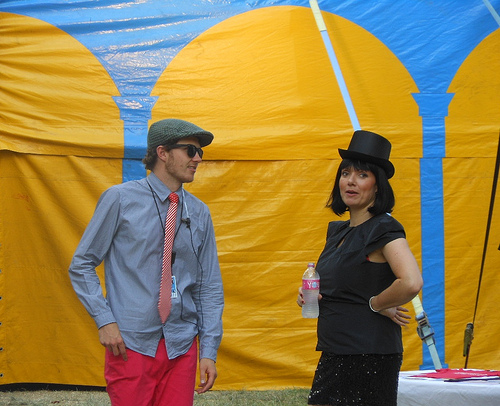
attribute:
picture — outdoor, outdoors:
[2, 1, 495, 403]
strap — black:
[453, 181, 496, 377]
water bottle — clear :
[297, 263, 319, 321]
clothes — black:
[303, 150, 433, 381]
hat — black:
[243, 95, 436, 209]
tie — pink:
[116, 216, 229, 302]